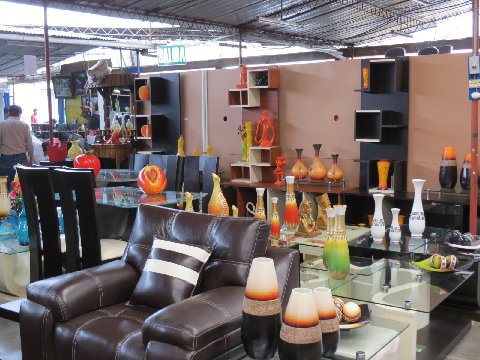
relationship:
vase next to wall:
[325, 151, 346, 183] [281, 62, 362, 183]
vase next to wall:
[307, 142, 326, 181] [281, 62, 362, 183]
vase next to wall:
[289, 148, 305, 177] [281, 62, 362, 183]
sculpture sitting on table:
[134, 163, 166, 195] [37, 175, 207, 237]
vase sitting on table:
[408, 179, 426, 236] [348, 221, 478, 270]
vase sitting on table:
[389, 207, 401, 244] [348, 221, 478, 270]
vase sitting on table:
[370, 191, 387, 241] [348, 221, 478, 270]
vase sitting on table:
[408, 180, 427, 245] [49, 185, 204, 227]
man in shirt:
[1, 109, 39, 188] [0, 126, 37, 160]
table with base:
[93, 175, 207, 227] [375, 279, 454, 332]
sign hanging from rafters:
[156, 43, 190, 64] [6, 4, 476, 68]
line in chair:
[140, 254, 203, 283] [18, 212, 301, 358]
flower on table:
[137, 162, 167, 196] [98, 188, 199, 202]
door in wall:
[359, 61, 410, 194] [400, 87, 418, 140]